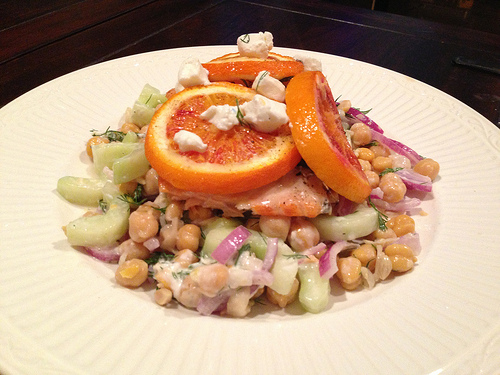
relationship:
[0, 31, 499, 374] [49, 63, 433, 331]
plate with food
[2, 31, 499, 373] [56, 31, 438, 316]
plate topped with salad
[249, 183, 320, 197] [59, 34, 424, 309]
sauce covering food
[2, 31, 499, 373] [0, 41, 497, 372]
plate sitting on table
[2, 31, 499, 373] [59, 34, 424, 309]
plate full of food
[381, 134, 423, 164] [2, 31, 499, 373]
onion on plate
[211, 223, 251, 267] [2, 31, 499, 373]
onion on plate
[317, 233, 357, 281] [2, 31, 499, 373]
onion on plate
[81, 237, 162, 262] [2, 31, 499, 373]
onion on plate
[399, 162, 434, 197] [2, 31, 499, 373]
onion on plate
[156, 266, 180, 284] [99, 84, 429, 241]
creamy substance in food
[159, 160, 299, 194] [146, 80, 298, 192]
orange rind laying on blood orange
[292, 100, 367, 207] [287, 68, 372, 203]
orange rind laying on blood orange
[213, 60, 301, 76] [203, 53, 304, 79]
orange rind laying on blood orange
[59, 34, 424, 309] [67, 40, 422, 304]
food on plate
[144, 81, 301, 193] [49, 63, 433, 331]
blood orange on top of food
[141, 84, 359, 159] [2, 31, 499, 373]
cheese on plate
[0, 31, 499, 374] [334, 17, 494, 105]
plate on table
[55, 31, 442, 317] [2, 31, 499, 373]
food on plate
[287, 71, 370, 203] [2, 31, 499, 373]
food on plate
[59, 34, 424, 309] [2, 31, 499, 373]
food on plate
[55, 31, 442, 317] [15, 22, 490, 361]
food on plate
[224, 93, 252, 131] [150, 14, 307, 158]
herb on cheese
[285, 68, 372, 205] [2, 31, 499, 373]
blood orange on plate